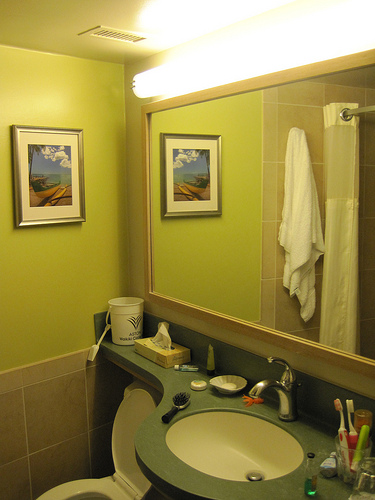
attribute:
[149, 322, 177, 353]
tissues — box, opened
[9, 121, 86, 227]
frame — print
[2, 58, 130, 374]
wall — bathroom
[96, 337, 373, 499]
counter — green, formica, hotel, bathroom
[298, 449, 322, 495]
mouthwash — small, vial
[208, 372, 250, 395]
dish — soap, fluted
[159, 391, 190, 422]
hairbrush — black, silver, plastic